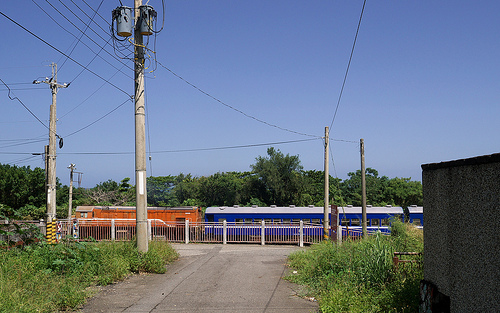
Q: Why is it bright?
A: The sun is out.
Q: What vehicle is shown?
A: A train.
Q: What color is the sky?
A: Blue.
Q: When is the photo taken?
A: In the daytime.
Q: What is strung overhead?
A: Power lines.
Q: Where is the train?
A: Behind the fence.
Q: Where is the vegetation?
A: Beside the road.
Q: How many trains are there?
A: One.